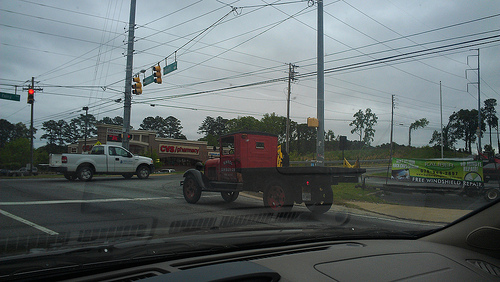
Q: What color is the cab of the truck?
A: Red.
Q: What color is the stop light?
A: Red.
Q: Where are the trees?
A: In the back of the picture.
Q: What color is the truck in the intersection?
A: White.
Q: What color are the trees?
A: Green.